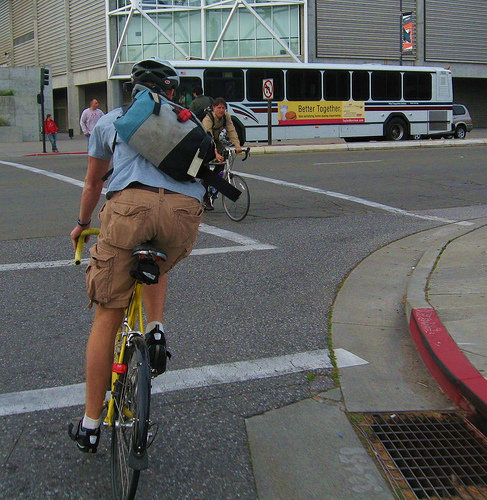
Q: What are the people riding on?
A: Bicycles.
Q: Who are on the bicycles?
A: Men.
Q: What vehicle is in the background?
A: A bus.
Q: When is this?
A: Daytime.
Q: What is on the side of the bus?
A: An advertisement.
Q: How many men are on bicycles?
A: Two.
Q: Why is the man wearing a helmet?
A: To protect his head.